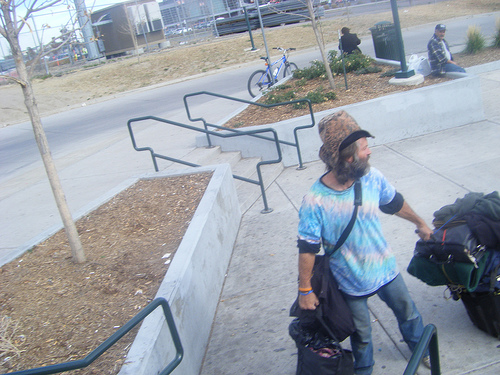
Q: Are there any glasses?
A: No, there are no glasses.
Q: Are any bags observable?
A: Yes, there is a bag.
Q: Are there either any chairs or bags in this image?
A: Yes, there is a bag.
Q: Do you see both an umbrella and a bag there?
A: No, there is a bag but no umbrellas.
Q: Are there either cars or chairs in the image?
A: No, there are no cars or chairs.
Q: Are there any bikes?
A: Yes, there is a bike.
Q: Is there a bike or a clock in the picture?
A: Yes, there is a bike.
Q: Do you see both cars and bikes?
A: No, there is a bike but no cars.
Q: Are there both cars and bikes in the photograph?
A: No, there is a bike but no cars.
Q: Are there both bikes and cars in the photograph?
A: No, there is a bike but no cars.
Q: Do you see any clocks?
A: No, there are no clocks.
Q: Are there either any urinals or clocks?
A: No, there are no clocks or urinals.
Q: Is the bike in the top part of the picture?
A: Yes, the bike is in the top of the image.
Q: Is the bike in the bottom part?
A: No, the bike is in the top of the image.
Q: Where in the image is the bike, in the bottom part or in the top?
A: The bike is in the top of the image.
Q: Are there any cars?
A: No, there are no cars.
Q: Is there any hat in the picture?
A: Yes, there is a hat.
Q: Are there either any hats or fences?
A: Yes, there is a hat.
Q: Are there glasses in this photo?
A: No, there are no glasses.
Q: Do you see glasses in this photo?
A: No, there are no glasses.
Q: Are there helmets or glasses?
A: No, there are no glasses or helmets.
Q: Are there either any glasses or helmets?
A: No, there are no glasses or helmets.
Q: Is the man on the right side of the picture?
A: Yes, the man is on the right of the image.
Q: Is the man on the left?
A: No, the man is on the right of the image.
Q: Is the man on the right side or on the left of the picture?
A: The man is on the right of the image.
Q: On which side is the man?
A: The man is on the right of the image.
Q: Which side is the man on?
A: The man is on the right of the image.